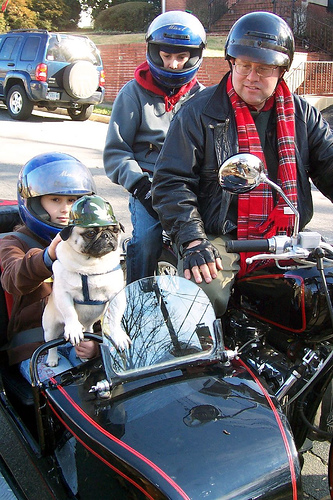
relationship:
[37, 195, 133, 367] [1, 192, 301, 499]
pug in sidecar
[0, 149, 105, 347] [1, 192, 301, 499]
kid in sidecar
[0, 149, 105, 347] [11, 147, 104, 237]
kid wearing a helmet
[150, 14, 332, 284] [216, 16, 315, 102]
man wearing a helmet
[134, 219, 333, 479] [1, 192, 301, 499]
motorcycle has a sidecar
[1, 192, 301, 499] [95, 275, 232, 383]
sidecar has a windshield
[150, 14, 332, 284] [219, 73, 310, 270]
man wearing a scarf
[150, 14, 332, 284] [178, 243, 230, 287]
man wearing gloves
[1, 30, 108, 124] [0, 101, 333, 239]
suv on road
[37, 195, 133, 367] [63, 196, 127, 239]
pug wearing a helmet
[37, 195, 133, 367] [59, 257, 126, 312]
pug wearing a harness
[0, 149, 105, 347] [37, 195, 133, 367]
kid holding pug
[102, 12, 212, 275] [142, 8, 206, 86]
boy wearing a helmet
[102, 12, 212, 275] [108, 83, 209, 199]
boy wearing a sweater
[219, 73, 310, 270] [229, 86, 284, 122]
scarf around neck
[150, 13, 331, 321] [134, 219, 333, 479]
man are on motorcycle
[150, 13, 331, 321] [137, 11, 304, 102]
man are wearing helmets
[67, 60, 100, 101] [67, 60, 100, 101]
tire in tire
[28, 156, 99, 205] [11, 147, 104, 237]
visor on helmet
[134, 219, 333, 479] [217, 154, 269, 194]
motorcycle has a rearview mirror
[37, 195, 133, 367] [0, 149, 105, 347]
pug being held by kid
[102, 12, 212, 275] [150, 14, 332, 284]
boy behind man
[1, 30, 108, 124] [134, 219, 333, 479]
suv behind motorcycle